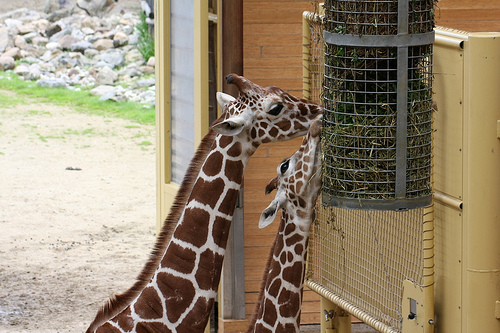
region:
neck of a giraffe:
[171, 210, 218, 286]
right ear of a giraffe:
[201, 113, 248, 144]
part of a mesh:
[331, 250, 383, 292]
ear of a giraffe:
[260, 205, 281, 228]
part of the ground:
[43, 205, 100, 267]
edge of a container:
[452, 96, 472, 154]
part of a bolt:
[317, 296, 333, 331]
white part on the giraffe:
[281, 282, 293, 294]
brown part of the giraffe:
[162, 284, 189, 314]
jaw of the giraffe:
[298, 157, 316, 208]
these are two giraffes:
[106, 76, 314, 331]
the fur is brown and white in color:
[180, 215, 223, 258]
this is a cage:
[324, 7, 421, 202]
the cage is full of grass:
[323, 0, 430, 202]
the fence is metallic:
[343, 31, 435, 46]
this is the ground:
[28, 168, 85, 322]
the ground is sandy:
[17, 155, 65, 237]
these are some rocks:
[33, 16, 123, 62]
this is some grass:
[62, 88, 87, 101]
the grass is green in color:
[124, 102, 136, 116]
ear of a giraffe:
[211, 105, 243, 149]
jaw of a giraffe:
[306, 162, 315, 197]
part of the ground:
[38, 235, 89, 293]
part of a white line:
[202, 193, 219, 238]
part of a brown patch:
[178, 210, 203, 242]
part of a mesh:
[351, 227, 400, 280]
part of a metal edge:
[316, 286, 358, 320]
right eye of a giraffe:
[262, 98, 284, 116]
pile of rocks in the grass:
[6, 9, 136, 124]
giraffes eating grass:
[200, 51, 477, 198]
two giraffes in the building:
[162, 67, 369, 331]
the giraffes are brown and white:
[175, 61, 310, 331]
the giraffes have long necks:
[170, 59, 405, 328]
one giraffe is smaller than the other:
[170, 78, 407, 331]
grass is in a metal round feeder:
[309, 11, 469, 223]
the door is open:
[123, 8, 224, 238]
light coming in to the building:
[5, 30, 159, 208]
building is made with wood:
[233, 7, 300, 71]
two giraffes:
[98, 52, 389, 322]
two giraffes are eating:
[72, 49, 469, 329]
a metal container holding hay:
[288, 0, 477, 261]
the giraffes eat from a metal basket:
[106, 31, 456, 329]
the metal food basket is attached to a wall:
[260, 2, 467, 258]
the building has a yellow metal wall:
[288, 7, 495, 332]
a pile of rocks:
[8, 5, 158, 150]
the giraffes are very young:
[71, 50, 343, 329]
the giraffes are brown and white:
[116, 53, 393, 328]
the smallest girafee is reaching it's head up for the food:
[244, 114, 374, 327]